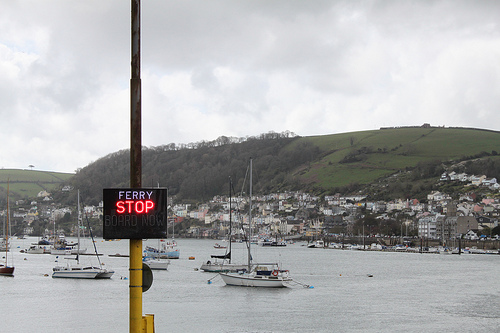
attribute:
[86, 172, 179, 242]
signal — traffic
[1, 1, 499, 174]
clouds — grey, white, low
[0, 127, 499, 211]
hill — big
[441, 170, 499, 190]
houses — large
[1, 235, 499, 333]
ocean — calm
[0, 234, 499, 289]
boats — small, anchored, moored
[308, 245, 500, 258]
pier — brown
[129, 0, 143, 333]
pole — yellow, metallic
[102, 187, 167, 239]
sign — electrical, illuminated, lit, ferry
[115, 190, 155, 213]
text — red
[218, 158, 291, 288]
sailboat — white, anchored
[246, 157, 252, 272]
tall mast — metallic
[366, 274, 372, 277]
duck — swimming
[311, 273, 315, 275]
duck — swimming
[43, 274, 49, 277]
duck — swimming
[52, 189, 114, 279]
sailboat — white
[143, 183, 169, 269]
sailboat — white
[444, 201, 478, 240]
building — tall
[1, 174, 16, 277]
sailboat — red, anchored